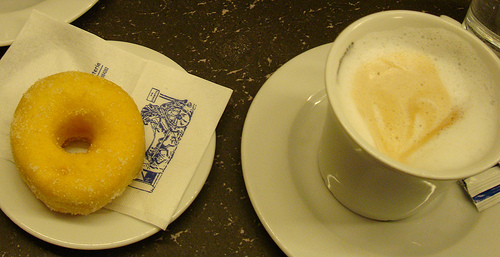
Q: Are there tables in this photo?
A: Yes, there is a table.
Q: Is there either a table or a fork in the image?
A: Yes, there is a table.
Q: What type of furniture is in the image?
A: The furniture is a table.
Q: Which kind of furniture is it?
A: The piece of furniture is a table.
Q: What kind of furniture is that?
A: This is a table.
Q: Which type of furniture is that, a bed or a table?
A: This is a table.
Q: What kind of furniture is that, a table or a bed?
A: This is a table.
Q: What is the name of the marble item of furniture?
A: The piece of furniture is a table.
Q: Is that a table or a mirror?
A: That is a table.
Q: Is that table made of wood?
A: No, the table is made of marble.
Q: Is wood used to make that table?
A: No, the table is made of marble.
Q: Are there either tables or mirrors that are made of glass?
A: No, there is a table but it is made of marble.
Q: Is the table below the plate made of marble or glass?
A: The table is made of marble.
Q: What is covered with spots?
A: The table is covered with spots.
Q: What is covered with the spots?
A: The table is covered with spots.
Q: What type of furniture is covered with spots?
A: The piece of furniture is a table.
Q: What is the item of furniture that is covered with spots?
A: The piece of furniture is a table.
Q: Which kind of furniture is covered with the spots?
A: The piece of furniture is a table.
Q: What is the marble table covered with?
A: The table is covered with spots.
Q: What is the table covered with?
A: The table is covered with spots.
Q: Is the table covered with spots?
A: Yes, the table is covered with spots.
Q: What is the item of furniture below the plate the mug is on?
A: The piece of furniture is a table.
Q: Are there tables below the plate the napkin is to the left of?
A: Yes, there is a table below the plate.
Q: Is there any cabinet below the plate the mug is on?
A: No, there is a table below the plate.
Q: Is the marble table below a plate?
A: Yes, the table is below a plate.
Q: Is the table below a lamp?
A: No, the table is below a plate.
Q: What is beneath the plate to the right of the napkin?
A: The table is beneath the plate.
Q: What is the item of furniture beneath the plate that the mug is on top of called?
A: The piece of furniture is a table.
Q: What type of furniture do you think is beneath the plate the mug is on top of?
A: The piece of furniture is a table.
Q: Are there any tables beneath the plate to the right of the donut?
A: Yes, there is a table beneath the plate.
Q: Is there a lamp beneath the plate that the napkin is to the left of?
A: No, there is a table beneath the plate.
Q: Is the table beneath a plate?
A: Yes, the table is beneath a plate.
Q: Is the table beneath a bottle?
A: No, the table is beneath a plate.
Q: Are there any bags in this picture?
A: Yes, there is a bag.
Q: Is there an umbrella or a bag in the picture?
A: Yes, there is a bag.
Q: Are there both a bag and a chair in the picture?
A: No, there is a bag but no chairs.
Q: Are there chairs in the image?
A: No, there are no chairs.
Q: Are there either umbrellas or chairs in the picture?
A: No, there are no chairs or umbrellas.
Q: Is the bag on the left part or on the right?
A: The bag is on the right of the image.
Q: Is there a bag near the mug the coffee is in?
A: Yes, there is a bag near the mug.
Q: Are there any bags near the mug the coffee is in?
A: Yes, there is a bag near the mug.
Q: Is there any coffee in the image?
A: Yes, there is coffee.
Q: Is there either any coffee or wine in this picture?
A: Yes, there is coffee.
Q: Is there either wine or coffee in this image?
A: Yes, there is coffee.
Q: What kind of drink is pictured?
A: The drink is coffee.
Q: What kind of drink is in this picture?
A: The drink is coffee.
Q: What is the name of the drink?
A: The drink is coffee.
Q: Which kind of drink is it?
A: The drink is coffee.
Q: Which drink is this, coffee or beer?
A: This is coffee.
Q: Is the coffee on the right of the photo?
A: Yes, the coffee is on the right of the image.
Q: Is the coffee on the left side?
A: No, the coffee is on the right of the image.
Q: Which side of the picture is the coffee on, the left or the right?
A: The coffee is on the right of the image.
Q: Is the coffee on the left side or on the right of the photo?
A: The coffee is on the right of the image.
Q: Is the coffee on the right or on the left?
A: The coffee is on the right of the image.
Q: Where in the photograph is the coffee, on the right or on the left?
A: The coffee is on the right of the image.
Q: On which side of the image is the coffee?
A: The coffee is on the right of the image.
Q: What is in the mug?
A: The coffee is in the mug.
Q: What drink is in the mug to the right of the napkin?
A: The drink is coffee.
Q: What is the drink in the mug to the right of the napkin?
A: The drink is coffee.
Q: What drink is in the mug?
A: The drink is coffee.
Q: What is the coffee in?
A: The coffee is in the mug.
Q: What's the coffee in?
A: The coffee is in the mug.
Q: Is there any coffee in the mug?
A: Yes, there is coffee in the mug.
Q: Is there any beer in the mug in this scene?
A: No, there is coffee in the mug.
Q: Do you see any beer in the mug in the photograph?
A: No, there is coffee in the mug.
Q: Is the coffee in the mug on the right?
A: Yes, the coffee is in the mug.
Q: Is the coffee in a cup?
A: No, the coffee is in the mug.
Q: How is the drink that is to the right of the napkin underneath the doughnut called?
A: The drink is coffee.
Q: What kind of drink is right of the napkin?
A: The drink is coffee.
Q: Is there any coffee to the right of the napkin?
A: Yes, there is coffee to the right of the napkin.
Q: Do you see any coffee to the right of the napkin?
A: Yes, there is coffee to the right of the napkin.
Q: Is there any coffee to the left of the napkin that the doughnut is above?
A: No, the coffee is to the right of the napkin.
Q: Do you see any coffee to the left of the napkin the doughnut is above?
A: No, the coffee is to the right of the napkin.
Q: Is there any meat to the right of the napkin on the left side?
A: No, there is coffee to the right of the napkin.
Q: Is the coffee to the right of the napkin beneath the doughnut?
A: Yes, the coffee is to the right of the napkin.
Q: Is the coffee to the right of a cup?
A: No, the coffee is to the right of the napkin.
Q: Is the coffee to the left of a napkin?
A: No, the coffee is to the right of a napkin.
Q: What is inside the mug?
A: The coffee is inside the mug.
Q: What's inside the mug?
A: The coffee is inside the mug.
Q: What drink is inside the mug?
A: The drink is coffee.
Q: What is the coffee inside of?
A: The coffee is inside the mug.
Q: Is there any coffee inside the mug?
A: Yes, there is coffee inside the mug.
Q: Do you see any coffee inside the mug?
A: Yes, there is coffee inside the mug.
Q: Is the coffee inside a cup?
A: No, the coffee is inside the mug.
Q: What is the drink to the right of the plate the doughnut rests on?
A: The drink is coffee.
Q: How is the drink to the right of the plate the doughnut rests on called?
A: The drink is coffee.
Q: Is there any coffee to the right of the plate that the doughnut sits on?
A: Yes, there is coffee to the right of the plate.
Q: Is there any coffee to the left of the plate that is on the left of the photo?
A: No, the coffee is to the right of the plate.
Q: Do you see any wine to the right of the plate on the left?
A: No, there is coffee to the right of the plate.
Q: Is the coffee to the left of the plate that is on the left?
A: No, the coffee is to the right of the plate.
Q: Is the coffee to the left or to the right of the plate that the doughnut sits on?
A: The coffee is to the right of the plate.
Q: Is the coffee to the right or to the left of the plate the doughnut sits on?
A: The coffee is to the right of the plate.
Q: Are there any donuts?
A: Yes, there is a donut.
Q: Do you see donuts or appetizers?
A: Yes, there is a donut.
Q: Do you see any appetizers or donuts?
A: Yes, there is a donut.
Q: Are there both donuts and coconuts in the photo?
A: No, there is a donut but no coconuts.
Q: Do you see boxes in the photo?
A: No, there are no boxes.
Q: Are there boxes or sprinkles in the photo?
A: No, there are no boxes or sprinkles.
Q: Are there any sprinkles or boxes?
A: No, there are no boxes or sprinkles.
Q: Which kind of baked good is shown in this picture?
A: The baked good is a donut.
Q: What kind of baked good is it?
A: The food is a donut.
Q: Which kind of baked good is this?
A: This is a donut.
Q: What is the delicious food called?
A: The food is a donut.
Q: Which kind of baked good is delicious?
A: The baked good is a donut.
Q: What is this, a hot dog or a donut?
A: This is a donut.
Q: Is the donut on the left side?
A: Yes, the donut is on the left of the image.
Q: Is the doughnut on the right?
A: No, the doughnut is on the left of the image.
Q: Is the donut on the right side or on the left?
A: The donut is on the left of the image.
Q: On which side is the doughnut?
A: The doughnut is on the left of the image.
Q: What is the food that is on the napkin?
A: The food is a donut.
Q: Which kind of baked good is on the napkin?
A: The food is a donut.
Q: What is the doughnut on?
A: The doughnut is on the napkin.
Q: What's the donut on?
A: The doughnut is on the napkin.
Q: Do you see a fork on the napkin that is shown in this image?
A: No, there is a donut on the napkin.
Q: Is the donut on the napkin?
A: Yes, the donut is on the napkin.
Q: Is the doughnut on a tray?
A: No, the doughnut is on the napkin.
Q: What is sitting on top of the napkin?
A: The donut is sitting on top of the napkin.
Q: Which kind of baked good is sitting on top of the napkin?
A: The food is a donut.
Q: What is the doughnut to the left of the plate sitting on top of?
A: The donut is sitting on top of the napkin.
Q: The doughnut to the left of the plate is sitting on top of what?
A: The donut is sitting on top of the napkin.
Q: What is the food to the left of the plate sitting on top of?
A: The donut is sitting on top of the napkin.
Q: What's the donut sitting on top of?
A: The donut is sitting on top of the napkin.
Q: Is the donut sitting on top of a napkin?
A: Yes, the donut is sitting on top of a napkin.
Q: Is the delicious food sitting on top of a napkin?
A: Yes, the donut is sitting on top of a napkin.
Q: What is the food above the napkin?
A: The food is a donut.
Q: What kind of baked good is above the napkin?
A: The food is a donut.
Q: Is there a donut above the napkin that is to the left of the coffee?
A: Yes, there is a donut above the napkin.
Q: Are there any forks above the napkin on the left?
A: No, there is a donut above the napkin.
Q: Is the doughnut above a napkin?
A: Yes, the doughnut is above a napkin.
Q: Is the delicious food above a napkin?
A: Yes, the doughnut is above a napkin.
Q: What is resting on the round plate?
A: The doughnut is resting on the plate.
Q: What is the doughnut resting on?
A: The doughnut is resting on the plate.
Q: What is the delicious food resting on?
A: The doughnut is resting on the plate.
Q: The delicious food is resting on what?
A: The doughnut is resting on the plate.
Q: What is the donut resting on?
A: The doughnut is resting on the plate.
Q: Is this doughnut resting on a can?
A: No, the doughnut is resting on the plate.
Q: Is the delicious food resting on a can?
A: No, the doughnut is resting on the plate.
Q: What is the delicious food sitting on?
A: The donut is sitting on the plate.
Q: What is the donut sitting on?
A: The donut is sitting on the plate.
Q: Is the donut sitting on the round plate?
A: Yes, the donut is sitting on the plate.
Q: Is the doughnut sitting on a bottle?
A: No, the doughnut is sitting on the plate.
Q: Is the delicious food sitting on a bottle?
A: No, the doughnut is sitting on the plate.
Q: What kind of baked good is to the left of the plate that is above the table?
A: The food is a donut.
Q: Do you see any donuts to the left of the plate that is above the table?
A: Yes, there is a donut to the left of the plate.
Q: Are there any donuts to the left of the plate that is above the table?
A: Yes, there is a donut to the left of the plate.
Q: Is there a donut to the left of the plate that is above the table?
A: Yes, there is a donut to the left of the plate.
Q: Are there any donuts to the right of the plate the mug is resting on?
A: No, the donut is to the left of the plate.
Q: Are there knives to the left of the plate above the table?
A: No, there is a donut to the left of the plate.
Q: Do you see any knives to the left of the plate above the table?
A: No, there is a donut to the left of the plate.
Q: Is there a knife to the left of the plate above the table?
A: No, there is a donut to the left of the plate.